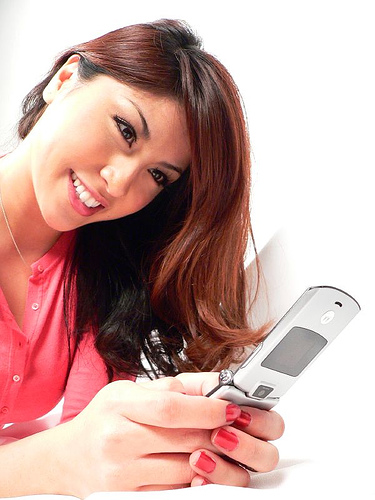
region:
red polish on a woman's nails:
[198, 403, 253, 491]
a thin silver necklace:
[0, 197, 29, 267]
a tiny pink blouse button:
[13, 373, 20, 380]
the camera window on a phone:
[253, 384, 271, 398]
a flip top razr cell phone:
[206, 284, 363, 409]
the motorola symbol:
[321, 309, 334, 324]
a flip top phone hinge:
[217, 369, 232, 387]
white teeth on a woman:
[70, 170, 104, 208]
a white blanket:
[3, 460, 345, 499]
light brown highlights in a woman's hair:
[150, 72, 274, 383]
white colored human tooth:
[72, 178, 82, 186]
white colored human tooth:
[76, 183, 82, 192]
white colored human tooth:
[78, 190, 88, 201]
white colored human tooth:
[85, 196, 94, 207]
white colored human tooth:
[92, 202, 96, 206]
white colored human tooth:
[69, 173, 76, 180]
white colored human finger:
[122, 384, 240, 429]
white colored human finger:
[135, 422, 219, 455]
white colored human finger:
[143, 452, 194, 483]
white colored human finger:
[235, 406, 286, 439]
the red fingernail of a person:
[225, 400, 240, 417]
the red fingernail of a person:
[234, 407, 249, 424]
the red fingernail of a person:
[213, 428, 237, 449]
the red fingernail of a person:
[191, 451, 215, 471]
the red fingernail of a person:
[199, 479, 210, 487]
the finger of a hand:
[112, 381, 232, 427]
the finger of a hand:
[132, 420, 227, 455]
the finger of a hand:
[138, 450, 202, 482]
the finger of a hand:
[234, 402, 284, 437]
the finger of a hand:
[212, 424, 276, 466]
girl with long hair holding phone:
[0, 15, 360, 496]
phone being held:
[208, 284, 361, 407]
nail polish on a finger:
[212, 426, 239, 452]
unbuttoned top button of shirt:
[36, 261, 44, 276]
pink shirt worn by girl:
[0, 231, 138, 432]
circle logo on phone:
[318, 309, 336, 328]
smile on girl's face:
[67, 163, 109, 218]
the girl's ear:
[40, 50, 81, 103]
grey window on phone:
[263, 327, 324, 377]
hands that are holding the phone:
[55, 370, 285, 490]